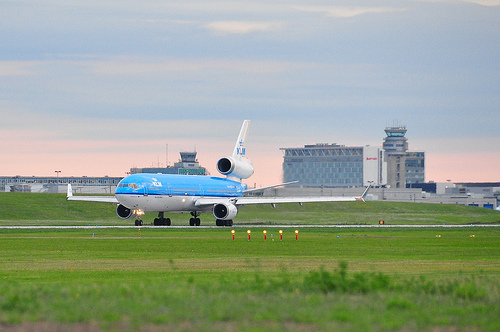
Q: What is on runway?
A: Plane.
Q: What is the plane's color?
A: Blue and white.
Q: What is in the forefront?
A: Grass.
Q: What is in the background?
A: Buildings.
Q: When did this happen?
A: During the day time.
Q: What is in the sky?
A: Clouds.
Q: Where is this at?
A: Airport.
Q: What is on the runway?
A: Plane.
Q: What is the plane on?
A: Runway.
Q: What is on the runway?
A: A large plane.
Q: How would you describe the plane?
A: Its blue and white.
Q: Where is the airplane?
A: Its on the ground.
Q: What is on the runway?
A: A blue and white airplane.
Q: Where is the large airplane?
A: Its on the runway.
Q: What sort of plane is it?
A: Its a passenger plane.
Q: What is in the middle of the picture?
A: An airplane on the runway.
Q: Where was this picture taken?
A: At an airport.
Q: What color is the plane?
A: Blue and white.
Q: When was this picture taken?
A: At dusk.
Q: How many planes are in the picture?
A: One.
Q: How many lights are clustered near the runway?
A: Five.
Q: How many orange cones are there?
A: One.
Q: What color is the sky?
A: Blue and pink.